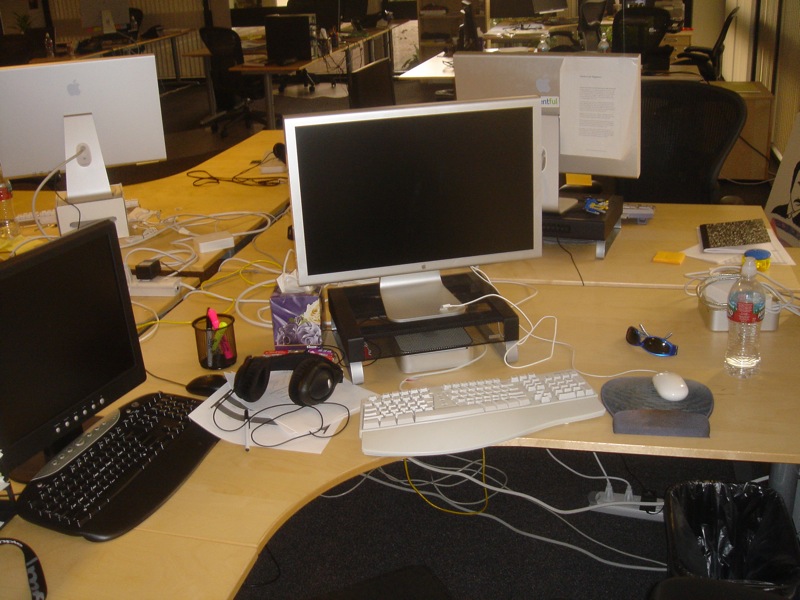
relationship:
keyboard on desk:
[18, 394, 226, 547] [3, 130, 799, 599]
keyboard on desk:
[357, 367, 608, 458] [3, 130, 799, 599]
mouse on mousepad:
[651, 367, 688, 403] [599, 372, 717, 443]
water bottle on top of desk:
[726, 260, 767, 370] [3, 130, 799, 599]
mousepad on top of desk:
[599, 372, 717, 443] [3, 130, 799, 599]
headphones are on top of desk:
[233, 350, 345, 406] [3, 130, 799, 599]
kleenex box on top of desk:
[270, 282, 323, 351] [3, 130, 799, 599]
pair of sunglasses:
[624, 323, 679, 359] [623, 323, 679, 357]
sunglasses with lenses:
[623, 323, 679, 357] [647, 337, 668, 352]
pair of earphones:
[237, 353, 340, 401] [233, 350, 345, 406]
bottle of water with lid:
[726, 260, 767, 370] [741, 260, 755, 279]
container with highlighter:
[193, 315, 241, 370] [206, 308, 236, 361]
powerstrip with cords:
[127, 262, 187, 299] [127, 244, 204, 282]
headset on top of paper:
[233, 350, 345, 406] [186, 365, 369, 457]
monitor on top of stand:
[278, 98, 548, 288] [327, 273, 521, 361]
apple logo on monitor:
[65, 80, 83, 98] [4, 53, 171, 205]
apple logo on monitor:
[536, 72, 553, 96] [447, 48, 644, 205]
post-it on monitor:
[562, 172, 598, 187] [447, 48, 644, 205]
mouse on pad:
[651, 367, 688, 403] [599, 372, 717, 443]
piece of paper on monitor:
[562, 172, 598, 187] [447, 48, 644, 205]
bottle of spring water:
[726, 260, 767, 370] [728, 318, 758, 366]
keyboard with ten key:
[357, 367, 608, 458] [367, 378, 589, 414]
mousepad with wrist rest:
[599, 372, 717, 443] [614, 409, 710, 436]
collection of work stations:
[4, 51, 711, 532] [1, 56, 656, 540]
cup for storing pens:
[193, 315, 241, 370] [203, 307, 228, 368]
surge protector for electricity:
[127, 262, 187, 299] [131, 211, 288, 305]